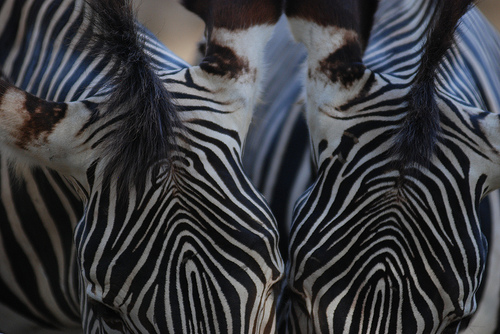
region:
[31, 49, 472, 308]
Two zebra head is focused.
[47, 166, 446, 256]
Zebra is white and black color.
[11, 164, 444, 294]
Zebra have stripe design in it.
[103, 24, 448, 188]
Short hairs found in zebra back.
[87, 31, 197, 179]
Hair is black color.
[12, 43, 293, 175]
Two pointed ears for zebra.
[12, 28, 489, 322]
Day time picture.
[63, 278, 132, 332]
Eyes are black color.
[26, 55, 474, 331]
Two heads of zebra are close together.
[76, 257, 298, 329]
Two eyes for zebra.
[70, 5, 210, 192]
the mane of a zebra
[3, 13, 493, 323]
a pair of zebras touching faces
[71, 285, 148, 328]
a zebra's eye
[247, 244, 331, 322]
two zebras looking very closely at each other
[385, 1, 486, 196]
a zebra's mane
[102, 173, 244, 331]
the pattern of zebra stripes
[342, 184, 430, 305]
black and white striped fur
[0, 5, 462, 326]
wildlife photography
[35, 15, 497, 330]
herd animals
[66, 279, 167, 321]
wrinkles from the zebra's eyelid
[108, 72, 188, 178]
black tuft of hair on a zebra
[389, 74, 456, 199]
wispy black zebra mane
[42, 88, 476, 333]
two zebras head to head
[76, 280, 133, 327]
eye of a zebra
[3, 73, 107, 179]
zebra ear with stripes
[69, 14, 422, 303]
zebra looking into a mirror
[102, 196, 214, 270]
stripes of a zebra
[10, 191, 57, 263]
black and white zebra pattern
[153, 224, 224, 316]
unique forehead pattern of zebra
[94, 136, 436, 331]
zebra staring at itself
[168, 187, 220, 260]
head of a zebra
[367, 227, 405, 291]
part of a zebra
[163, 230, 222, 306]
part of a zebra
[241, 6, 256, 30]
part of an edge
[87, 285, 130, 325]
edge of an eye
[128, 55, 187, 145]
part of some hair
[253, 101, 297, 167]
stomach of a zebra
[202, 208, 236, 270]
part of a zebra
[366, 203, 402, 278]
head of a zebra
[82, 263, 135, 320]
edge of an eye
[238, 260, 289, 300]
edge of an eyelid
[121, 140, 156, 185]
part of some hair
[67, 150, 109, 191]
edge of an ear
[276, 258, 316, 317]
edge of an eye